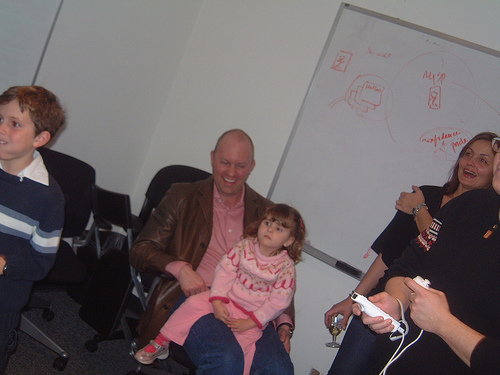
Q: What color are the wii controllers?
A: White.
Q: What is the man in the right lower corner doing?
A: Play the wii.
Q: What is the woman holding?
A: A drink.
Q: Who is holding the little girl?
A: Man in a brown coat.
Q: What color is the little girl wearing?
A: Pink.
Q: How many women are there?
A: One.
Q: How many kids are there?
A: 2.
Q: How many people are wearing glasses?
A: One.